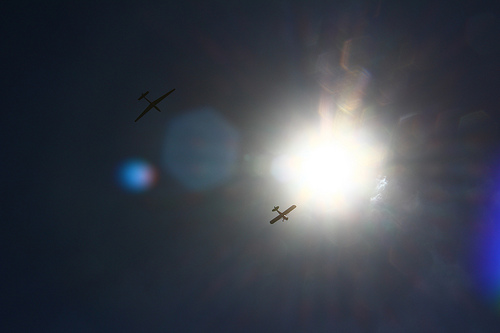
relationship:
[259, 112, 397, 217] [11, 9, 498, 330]
sun in sky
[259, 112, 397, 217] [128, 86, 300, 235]
sun above of airplanes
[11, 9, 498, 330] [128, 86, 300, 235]
sky above airplanes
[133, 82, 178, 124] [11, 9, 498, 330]
airplane in sky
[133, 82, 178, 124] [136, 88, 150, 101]
airplane has tail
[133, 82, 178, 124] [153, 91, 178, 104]
airplane has wings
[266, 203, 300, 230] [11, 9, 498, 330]
airplane in sky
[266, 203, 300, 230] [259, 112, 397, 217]
airplane beneath of sun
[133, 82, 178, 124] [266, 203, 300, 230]
airplane following airplane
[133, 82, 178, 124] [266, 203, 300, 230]
plane towing plane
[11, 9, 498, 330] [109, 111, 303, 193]
picture has sun spots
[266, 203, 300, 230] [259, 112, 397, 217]
airplane near to sun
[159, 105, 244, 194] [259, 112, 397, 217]
spot near to sun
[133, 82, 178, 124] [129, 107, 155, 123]
airplane has a wing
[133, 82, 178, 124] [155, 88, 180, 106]
airplane has a wing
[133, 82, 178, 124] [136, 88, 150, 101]
airplane has a tail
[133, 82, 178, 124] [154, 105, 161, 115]
airplane has nose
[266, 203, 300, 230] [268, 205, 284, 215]
airplane has tail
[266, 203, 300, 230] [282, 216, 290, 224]
airplane has nose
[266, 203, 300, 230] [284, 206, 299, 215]
airplane has wing